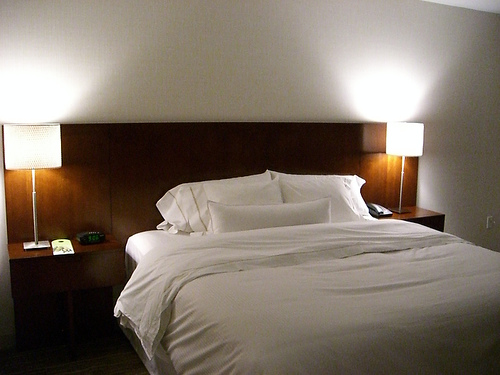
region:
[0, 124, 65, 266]
a lamp on a night stand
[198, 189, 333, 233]
a pillow on a bed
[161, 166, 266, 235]
a pillowcase on a pillow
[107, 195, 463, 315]
a sheet on a bed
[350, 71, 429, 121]
the light reflecting on the wall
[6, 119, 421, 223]
the headboard of a bed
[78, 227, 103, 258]
a alarm clock on the night stand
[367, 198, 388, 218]
a phone by the bed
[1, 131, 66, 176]
the shade of a lamp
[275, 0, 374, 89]
a wall in the room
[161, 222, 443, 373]
this is a bed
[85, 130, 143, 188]
the bed is wooden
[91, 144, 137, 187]
the bed is brown in color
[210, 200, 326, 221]
this is the pillow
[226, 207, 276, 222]
the pillow is white in color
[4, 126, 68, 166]
this is a lump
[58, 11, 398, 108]
this is the wall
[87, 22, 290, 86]
the wall is white in color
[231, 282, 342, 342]
this is the bed sheet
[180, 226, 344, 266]
this is the blanket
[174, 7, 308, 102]
The wall is white.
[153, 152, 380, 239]
The pillows are white.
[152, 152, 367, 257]
Four pillows are on the bed.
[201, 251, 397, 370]
The bed is white.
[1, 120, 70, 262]
The lamp is on.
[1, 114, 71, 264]
The lamp is white.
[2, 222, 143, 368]
The desk is made of wood.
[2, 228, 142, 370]
The desk is brown.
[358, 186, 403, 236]
A phone is on the stand.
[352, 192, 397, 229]
The phone is gray.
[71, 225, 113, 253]
Small black alarm clock with green writing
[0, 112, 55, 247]
Bright white lamp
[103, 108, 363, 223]
Brown wooden head board to a white bed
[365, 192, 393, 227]
Gray land line phone on a brown night stand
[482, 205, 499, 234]
Small white outlet on a wall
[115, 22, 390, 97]
Plain white wall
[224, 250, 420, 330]
White bed sheets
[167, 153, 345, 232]
Multiple white pillows with gold trim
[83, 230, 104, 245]
Green writing that says 9:00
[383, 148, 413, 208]
Metal pole of a lamp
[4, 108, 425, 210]
Brown wooden headboard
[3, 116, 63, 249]
Desk lamp on left desk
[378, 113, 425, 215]
Desk lamp on right desk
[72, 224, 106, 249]
Digital alarm clock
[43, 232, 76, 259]
Door hanger for hotel door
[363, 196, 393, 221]
Silver phone on right dresser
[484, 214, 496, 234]
Electrical wall socket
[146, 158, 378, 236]
White pillows on the bed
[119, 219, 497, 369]
White sheets and covers on the bed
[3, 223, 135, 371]
Wooden dresser on the left side of the bed